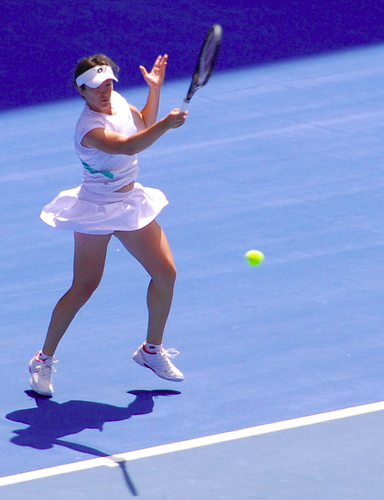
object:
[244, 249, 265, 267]
ball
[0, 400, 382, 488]
line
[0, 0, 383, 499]
ground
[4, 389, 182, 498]
shadow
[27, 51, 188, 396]
woman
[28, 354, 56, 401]
foot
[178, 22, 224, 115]
racket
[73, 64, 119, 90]
hat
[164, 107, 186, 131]
hand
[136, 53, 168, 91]
hand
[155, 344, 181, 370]
laces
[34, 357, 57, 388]
laces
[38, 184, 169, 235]
skirt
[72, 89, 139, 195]
shirt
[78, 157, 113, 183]
stripe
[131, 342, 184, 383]
foot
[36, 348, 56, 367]
sock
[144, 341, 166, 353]
sock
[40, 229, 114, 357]
legs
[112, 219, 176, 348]
legs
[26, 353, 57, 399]
shoe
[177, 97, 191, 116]
grip